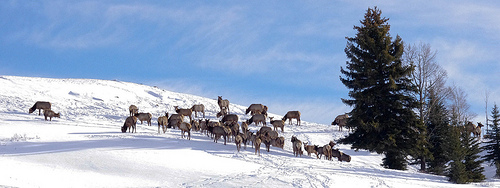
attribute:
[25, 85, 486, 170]
deer are seen — white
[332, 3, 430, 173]
pine tree — green, large, bare, tall, small, evergreen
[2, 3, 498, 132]
sky is blue — clear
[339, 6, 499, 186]
trees — evergreen, deciduous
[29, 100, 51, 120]
animal — baby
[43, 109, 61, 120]
animal — mom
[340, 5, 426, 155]
evergreen — very tall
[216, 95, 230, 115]
antelope — standing